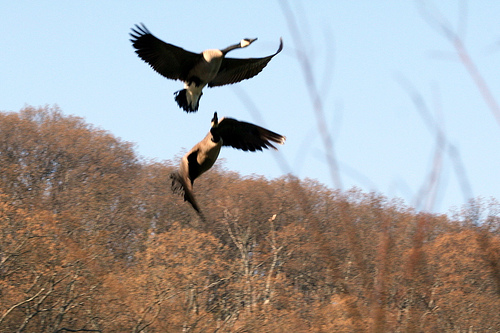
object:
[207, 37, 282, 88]
left wing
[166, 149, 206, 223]
wing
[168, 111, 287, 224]
bird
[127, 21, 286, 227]
mating ritual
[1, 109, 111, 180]
leaves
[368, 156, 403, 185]
ground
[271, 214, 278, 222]
bird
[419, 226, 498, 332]
trees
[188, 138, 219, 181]
bird's body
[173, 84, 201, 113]
feathers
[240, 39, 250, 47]
cheek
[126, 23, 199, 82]
wing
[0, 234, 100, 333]
trees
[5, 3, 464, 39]
sky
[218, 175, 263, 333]
tree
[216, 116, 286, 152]
wing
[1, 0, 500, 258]
blue sky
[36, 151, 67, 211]
branches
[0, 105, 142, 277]
tree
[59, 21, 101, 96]
clouds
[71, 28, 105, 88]
clouds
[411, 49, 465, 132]
clouds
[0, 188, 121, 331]
leaves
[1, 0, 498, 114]
sky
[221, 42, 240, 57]
neck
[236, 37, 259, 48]
head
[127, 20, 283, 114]
bird